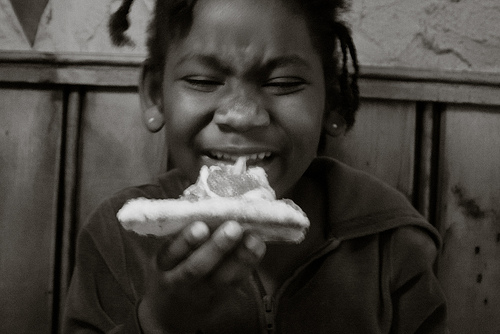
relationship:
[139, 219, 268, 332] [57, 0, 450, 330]
hand belonging to child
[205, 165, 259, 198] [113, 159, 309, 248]
pepperoni topping pizza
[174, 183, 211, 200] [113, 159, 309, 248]
pepperoni topping pizza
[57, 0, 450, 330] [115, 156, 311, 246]
child eating pizza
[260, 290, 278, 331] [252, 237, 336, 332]
pull tab attached to zipper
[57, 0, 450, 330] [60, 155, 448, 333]
child wearing sweater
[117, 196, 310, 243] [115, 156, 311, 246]
crust bordering pizza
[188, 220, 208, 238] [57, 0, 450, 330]
fingernail belonging to child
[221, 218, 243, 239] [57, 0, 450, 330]
fingernail belonging to child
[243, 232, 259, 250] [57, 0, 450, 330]
fingernail belonging to child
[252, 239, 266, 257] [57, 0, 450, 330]
fingernail belonging to child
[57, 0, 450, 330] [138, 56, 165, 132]
child has ear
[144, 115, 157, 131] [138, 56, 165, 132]
earring in ear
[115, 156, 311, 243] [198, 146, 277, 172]
pizza in front of mouth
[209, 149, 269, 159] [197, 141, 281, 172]
teeth in mouth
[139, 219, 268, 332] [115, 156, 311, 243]
hand holding pizza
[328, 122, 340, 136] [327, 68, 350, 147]
earring in ear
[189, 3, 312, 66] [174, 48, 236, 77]
forehead above eyebrow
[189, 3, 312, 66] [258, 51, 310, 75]
forehead above eyebrow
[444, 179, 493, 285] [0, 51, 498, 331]
marks on paneling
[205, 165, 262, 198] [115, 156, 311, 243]
pepperoni on pizza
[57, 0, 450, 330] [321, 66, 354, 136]
child has ear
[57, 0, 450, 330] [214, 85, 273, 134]
child has nose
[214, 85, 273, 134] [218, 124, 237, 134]
nose has nostril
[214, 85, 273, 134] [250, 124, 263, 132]
nose has nostril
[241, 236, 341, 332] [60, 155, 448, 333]
zipper on sweater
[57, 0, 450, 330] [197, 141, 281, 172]
child has mouth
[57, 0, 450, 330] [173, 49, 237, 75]
child has eyebrow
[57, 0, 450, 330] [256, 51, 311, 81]
child has eyebrow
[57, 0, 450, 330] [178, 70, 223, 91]
child has eye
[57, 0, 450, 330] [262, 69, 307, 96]
child has eye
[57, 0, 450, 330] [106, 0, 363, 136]
child has hair